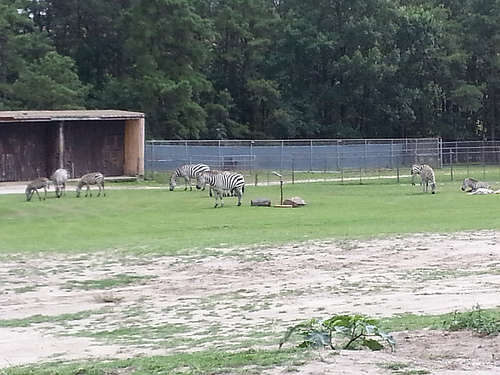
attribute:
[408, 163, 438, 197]
zebra — black and white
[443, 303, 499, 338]
leaves —  small ,  green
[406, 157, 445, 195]
zebra — black and white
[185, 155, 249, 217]
zebra — black and white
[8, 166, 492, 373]
grass — field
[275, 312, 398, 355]
plants —  small 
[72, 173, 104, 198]
zebra — black and white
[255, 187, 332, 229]
rocks —  two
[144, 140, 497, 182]
fencing — metal, security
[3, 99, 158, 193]
wooden shed —  wooden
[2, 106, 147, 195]
wooden shed —  wooden,  divided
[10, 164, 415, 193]
dirt path —  dirt 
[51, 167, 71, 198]
zebra — black, white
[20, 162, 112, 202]
zebras —  three,  together,  grazing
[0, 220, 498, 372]
patches —  dirt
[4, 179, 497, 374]
field — of zebras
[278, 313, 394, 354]
plant — growing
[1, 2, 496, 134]
green trees —  green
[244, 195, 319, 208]
rocks — small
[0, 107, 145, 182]
structure — wooden, cover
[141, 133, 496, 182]
fence —  long ,  metal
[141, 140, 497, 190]
fence —   metal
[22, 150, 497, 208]
group — large